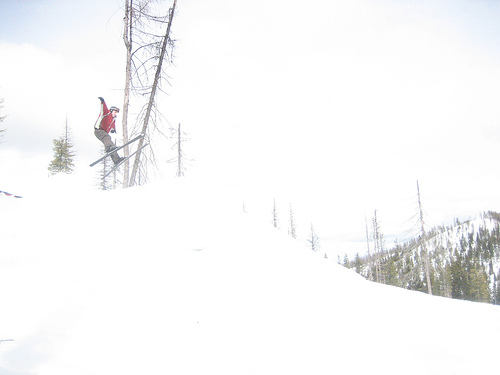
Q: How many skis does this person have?
A: 2.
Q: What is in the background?
A: Trees and Snow.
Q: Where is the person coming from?
A: The left.